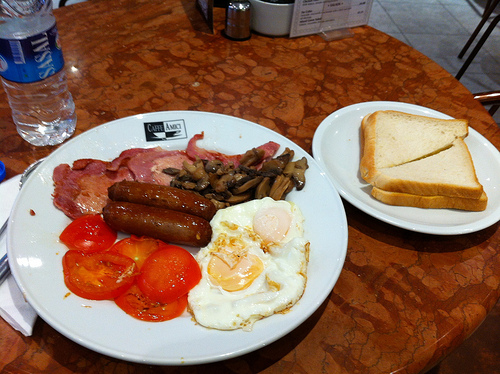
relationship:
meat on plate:
[50, 160, 137, 221] [7, 110, 347, 364]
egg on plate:
[187, 196, 312, 331] [7, 110, 347, 364]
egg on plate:
[187, 196, 312, 331] [313, 97, 498, 236]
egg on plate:
[187, 233, 307, 328] [7, 110, 347, 364]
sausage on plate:
[105, 177, 214, 237] [7, 110, 347, 364]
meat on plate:
[99, 140, 311, 195] [88, 101, 299, 161]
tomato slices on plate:
[58, 212, 118, 255] [7, 110, 347, 364]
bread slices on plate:
[337, 101, 483, 244] [303, 76, 370, 173]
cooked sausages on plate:
[101, 179, 218, 249] [7, 110, 347, 364]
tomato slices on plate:
[136, 240, 207, 301] [7, 110, 347, 364]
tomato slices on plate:
[62, 248, 139, 298] [7, 110, 347, 364]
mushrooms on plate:
[161, 143, 312, 204] [7, 110, 347, 364]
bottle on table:
[0, 1, 78, 144] [0, 1, 499, 372]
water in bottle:
[5, 8, 78, 148] [0, 1, 78, 144]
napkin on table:
[3, 285, 28, 320] [348, 271, 425, 321]